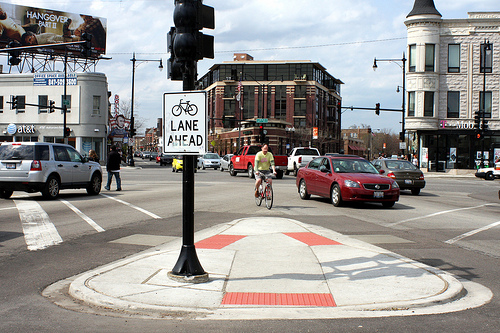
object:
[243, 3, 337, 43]
sky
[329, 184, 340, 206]
tire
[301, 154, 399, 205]
car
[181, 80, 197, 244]
pole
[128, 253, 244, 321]
ground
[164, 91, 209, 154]
sign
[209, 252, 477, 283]
shadow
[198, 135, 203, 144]
writing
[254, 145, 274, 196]
man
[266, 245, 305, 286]
concrete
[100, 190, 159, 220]
line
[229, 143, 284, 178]
suv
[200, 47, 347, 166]
building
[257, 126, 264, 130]
light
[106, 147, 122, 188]
pedestrian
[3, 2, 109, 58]
billboard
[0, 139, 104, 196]
car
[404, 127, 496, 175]
store